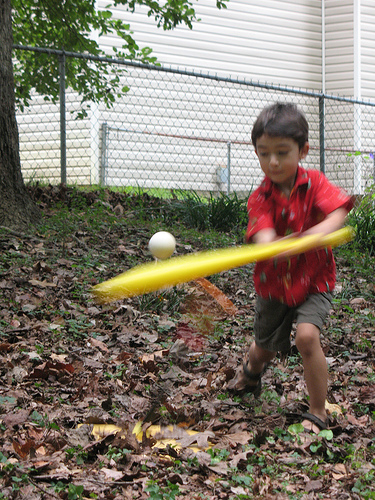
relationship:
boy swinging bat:
[232, 102, 354, 421] [92, 225, 352, 301]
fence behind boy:
[11, 41, 373, 194] [232, 102, 354, 421]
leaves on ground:
[0, 258, 374, 499] [0, 183, 374, 499]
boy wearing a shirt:
[232, 102, 354, 421] [244, 163, 351, 304]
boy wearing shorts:
[232, 102, 354, 421] [252, 296, 331, 354]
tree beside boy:
[1, 0, 219, 224] [232, 102, 354, 421]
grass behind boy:
[45, 181, 374, 260] [232, 102, 354, 421]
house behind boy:
[11, 41, 373, 194] [232, 102, 354, 421]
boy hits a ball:
[232, 102, 354, 421] [149, 230, 178, 262]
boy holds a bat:
[232, 102, 354, 421] [92, 225, 352, 301]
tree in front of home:
[1, 0, 219, 224] [14, 1, 373, 190]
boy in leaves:
[232, 102, 354, 421] [0, 258, 374, 499]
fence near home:
[11, 41, 373, 194] [14, 1, 373, 190]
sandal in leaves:
[296, 409, 326, 441] [0, 258, 374, 499]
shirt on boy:
[244, 163, 351, 304] [232, 102, 354, 421]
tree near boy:
[1, 0, 219, 224] [232, 102, 354, 421]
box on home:
[212, 165, 228, 185] [14, 1, 373, 190]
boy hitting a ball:
[232, 102, 354, 421] [149, 230, 178, 262]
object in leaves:
[76, 419, 206, 458] [0, 258, 374, 499]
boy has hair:
[232, 102, 354, 421] [250, 102, 311, 152]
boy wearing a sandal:
[232, 102, 354, 421] [296, 409, 326, 441]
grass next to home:
[45, 181, 374, 260] [14, 1, 373, 190]